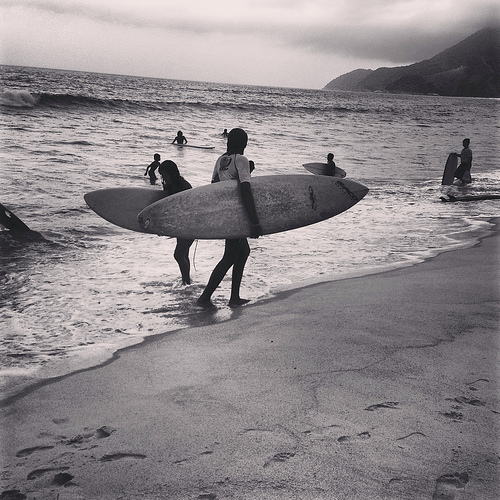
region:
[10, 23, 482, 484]
the picture is black and white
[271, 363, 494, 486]
foot prints in the sand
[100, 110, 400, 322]
people are surfing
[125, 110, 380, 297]
people are holding a surfboard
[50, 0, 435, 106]
the sky is overcast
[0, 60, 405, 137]
the waves are building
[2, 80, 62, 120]
the wave is white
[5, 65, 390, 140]
the waves are in motion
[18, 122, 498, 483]
a black and white picture of the beach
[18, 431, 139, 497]
footprints in the sand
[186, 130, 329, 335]
a man carrying a surfboard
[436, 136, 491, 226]
a young girl with a boogie board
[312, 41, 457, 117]
a mountain rising out of the water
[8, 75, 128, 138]
a wave cresting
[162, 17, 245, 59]
a cloudy sky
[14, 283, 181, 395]
foamy water on the sand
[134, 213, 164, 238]
tie for a surfboard leash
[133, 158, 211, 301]
a young girl carrying a surfboard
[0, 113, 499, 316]
Some surfers on the beach and in the water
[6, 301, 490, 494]
Sand with footprints in it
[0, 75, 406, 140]
Wave cresting in ocean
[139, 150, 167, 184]
Little child in the water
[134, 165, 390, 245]
White surfboard with design on bottom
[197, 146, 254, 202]
White compression swim shirt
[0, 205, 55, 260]
Surfboard partially submerged in the water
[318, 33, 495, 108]
Mountains in the distance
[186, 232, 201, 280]
Cord of surfboard so don't lose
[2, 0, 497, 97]
Clouds that look like rain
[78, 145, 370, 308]
people carrying surfboards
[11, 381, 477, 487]
footprints in the sand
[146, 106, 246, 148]
people surfing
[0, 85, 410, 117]
a wave coming in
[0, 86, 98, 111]
wave is cresting and crashing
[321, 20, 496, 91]
mountains in the distance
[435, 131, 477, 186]
man standing in water holding surfboard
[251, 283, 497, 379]
waves left markings in the sand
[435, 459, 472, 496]
large footprint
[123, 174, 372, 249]
surfboard under the arm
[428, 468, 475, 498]
footprint in the sand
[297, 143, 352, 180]
person holding a surfboard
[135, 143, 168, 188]
person in the water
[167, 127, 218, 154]
person standing by a board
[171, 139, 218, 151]
surfboard laying on the water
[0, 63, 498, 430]
a body of water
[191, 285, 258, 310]
feet in the water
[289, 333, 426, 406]
cracks in the sand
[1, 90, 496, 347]
people at the beach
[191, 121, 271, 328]
a Person carrying a surfboard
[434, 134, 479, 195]
a Person holding a surfboard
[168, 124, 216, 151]
A person ready to mount a surfboard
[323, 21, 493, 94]
Mountains in the background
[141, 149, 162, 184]
A young person walking in the surf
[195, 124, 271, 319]
A surfer walking along the beach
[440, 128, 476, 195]
A surfer watching for a wave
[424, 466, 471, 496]
A footprint in the sand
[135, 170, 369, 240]
surfboard is being carried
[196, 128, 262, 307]
the person is barefoot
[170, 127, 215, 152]
person is in the water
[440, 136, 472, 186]
person is standing in the water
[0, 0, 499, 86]
the sky is overcast